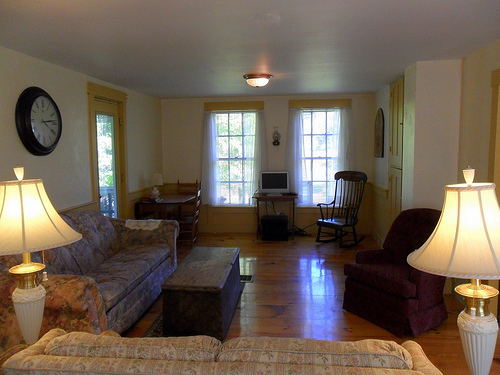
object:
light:
[241, 72, 271, 88]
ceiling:
[0, 0, 500, 98]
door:
[388, 77, 404, 239]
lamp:
[406, 166, 500, 373]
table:
[133, 179, 202, 249]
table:
[251, 189, 299, 238]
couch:
[0, 327, 444, 374]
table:
[159, 246, 240, 334]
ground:
[406, 158, 431, 182]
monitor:
[258, 171, 290, 196]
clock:
[14, 86, 64, 156]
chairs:
[316, 170, 367, 248]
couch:
[0, 211, 179, 333]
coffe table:
[161, 247, 240, 340]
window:
[208, 109, 256, 206]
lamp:
[0, 163, 83, 345]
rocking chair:
[315, 170, 366, 247]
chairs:
[164, 179, 201, 247]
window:
[294, 106, 346, 206]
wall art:
[372, 107, 385, 157]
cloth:
[125, 219, 162, 231]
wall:
[0, 64, 460, 210]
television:
[258, 166, 289, 196]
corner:
[343, 208, 449, 337]